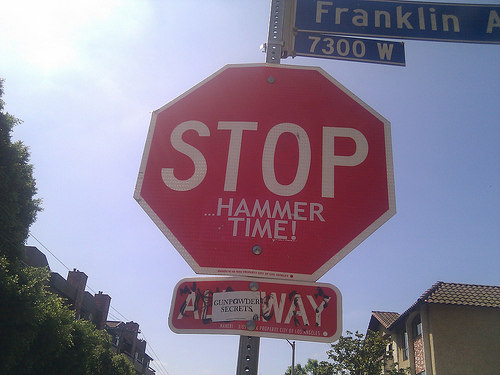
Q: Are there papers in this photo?
A: No, there are no papers.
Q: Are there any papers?
A: No, there are no papers.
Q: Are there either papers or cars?
A: No, there are no papers or cars.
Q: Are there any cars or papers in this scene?
A: No, there are no papers or cars.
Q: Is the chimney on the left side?
A: Yes, the chimney is on the left of the image.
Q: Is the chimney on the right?
A: No, the chimney is on the left of the image.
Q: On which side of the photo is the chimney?
A: The chimney is on the left of the image.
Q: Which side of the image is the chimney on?
A: The chimney is on the left of the image.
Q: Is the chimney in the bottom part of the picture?
A: Yes, the chimney is in the bottom of the image.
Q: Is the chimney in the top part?
A: No, the chimney is in the bottom of the image.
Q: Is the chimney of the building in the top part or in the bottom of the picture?
A: The chimney is in the bottom of the image.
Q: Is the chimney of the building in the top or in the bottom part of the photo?
A: The chimney is in the bottom of the image.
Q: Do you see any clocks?
A: No, there are no clocks.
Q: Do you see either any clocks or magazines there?
A: No, there are no clocks or magazines.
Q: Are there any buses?
A: No, there are no buses.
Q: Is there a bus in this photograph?
A: No, there are no buses.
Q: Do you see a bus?
A: No, there are no buses.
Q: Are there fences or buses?
A: No, there are no buses or fences.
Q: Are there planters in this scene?
A: No, there are no planters.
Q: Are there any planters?
A: No, there are no planters.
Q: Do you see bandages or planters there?
A: No, there are no planters or bandages.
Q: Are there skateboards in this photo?
A: No, there are no skateboards.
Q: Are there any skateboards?
A: No, there are no skateboards.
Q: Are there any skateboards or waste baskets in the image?
A: No, there are no skateboards or waste baskets.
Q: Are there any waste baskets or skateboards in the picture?
A: No, there are no skateboards or waste baskets.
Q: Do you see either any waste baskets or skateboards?
A: No, there are no skateboards or waste baskets.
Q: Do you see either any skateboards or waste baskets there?
A: No, there are no skateboards or waste baskets.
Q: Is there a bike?
A: No, there are no bikes.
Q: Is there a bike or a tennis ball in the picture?
A: No, there are no bikes or tennis balls.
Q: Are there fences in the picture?
A: No, there are no fences.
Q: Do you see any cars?
A: No, there are no cars.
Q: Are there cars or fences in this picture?
A: No, there are no cars or fences.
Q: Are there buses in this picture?
A: No, there are no buses.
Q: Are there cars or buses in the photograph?
A: No, there are no buses or cars.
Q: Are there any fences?
A: No, there are no fences.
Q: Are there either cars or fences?
A: No, there are no fences or cars.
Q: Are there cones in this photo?
A: No, there are no cones.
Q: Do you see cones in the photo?
A: No, there are no cones.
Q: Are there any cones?
A: No, there are no cones.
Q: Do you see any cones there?
A: No, there are no cones.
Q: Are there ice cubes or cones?
A: No, there are no cones or ice cubes.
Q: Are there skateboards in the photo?
A: No, there are no skateboards.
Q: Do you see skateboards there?
A: No, there are no skateboards.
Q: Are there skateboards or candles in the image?
A: No, there are no skateboards or candles.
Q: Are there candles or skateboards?
A: No, there are no skateboards or candles.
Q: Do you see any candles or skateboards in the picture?
A: No, there are no skateboards or candles.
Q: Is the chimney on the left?
A: Yes, the chimney is on the left of the image.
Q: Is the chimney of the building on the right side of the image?
A: No, the chimney is on the left of the image.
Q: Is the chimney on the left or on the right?
A: The chimney is on the left of the image.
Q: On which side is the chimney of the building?
A: The chimney is on the left of the image.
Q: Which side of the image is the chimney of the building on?
A: The chimney is on the left of the image.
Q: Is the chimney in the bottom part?
A: Yes, the chimney is in the bottom of the image.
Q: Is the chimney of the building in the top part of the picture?
A: No, the chimney is in the bottom of the image.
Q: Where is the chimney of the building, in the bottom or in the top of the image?
A: The chimney is in the bottom of the image.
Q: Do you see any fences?
A: No, there are no fences.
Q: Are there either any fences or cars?
A: No, there are no fences or cars.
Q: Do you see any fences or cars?
A: No, there are no fences or cars.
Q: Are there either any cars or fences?
A: No, there are no fences or cars.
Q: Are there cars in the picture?
A: No, there are no cars.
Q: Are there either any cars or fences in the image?
A: No, there are no cars or fences.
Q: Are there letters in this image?
A: Yes, there are letters.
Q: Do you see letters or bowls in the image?
A: Yes, there are letters.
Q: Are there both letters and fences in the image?
A: No, there are letters but no fences.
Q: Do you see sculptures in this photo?
A: No, there are no sculptures.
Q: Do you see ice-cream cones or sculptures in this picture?
A: No, there are no sculptures or ice-cream cones.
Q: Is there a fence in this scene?
A: No, there are no fences.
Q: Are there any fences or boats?
A: No, there are no fences or boats.